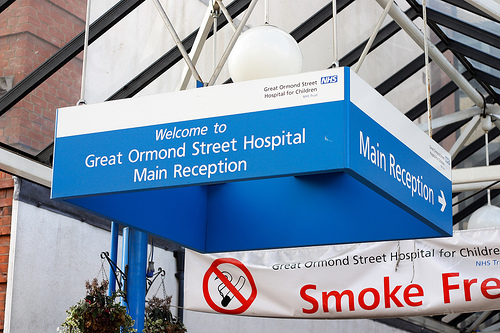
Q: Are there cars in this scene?
A: No, there are no cars.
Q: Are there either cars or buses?
A: No, there are no cars or buses.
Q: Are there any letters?
A: Yes, there are letters.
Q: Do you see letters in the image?
A: Yes, there are letters.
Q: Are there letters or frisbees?
A: Yes, there are letters.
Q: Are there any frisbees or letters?
A: Yes, there are letters.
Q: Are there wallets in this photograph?
A: No, there are no wallets.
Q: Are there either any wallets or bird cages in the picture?
A: No, there are no wallets or bird cages.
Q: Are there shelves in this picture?
A: No, there are no shelves.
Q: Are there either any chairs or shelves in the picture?
A: No, there are no shelves or chairs.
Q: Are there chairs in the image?
A: No, there are no chairs.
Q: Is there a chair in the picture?
A: No, there are no chairs.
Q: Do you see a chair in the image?
A: No, there are no chairs.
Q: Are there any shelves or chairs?
A: No, there are no chairs or shelves.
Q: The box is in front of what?
A: The box is in front of the wall.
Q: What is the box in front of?
A: The box is in front of the wall.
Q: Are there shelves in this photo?
A: No, there are no shelves.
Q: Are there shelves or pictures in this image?
A: No, there are no shelves or pictures.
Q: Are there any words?
A: Yes, there are words.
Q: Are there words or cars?
A: Yes, there are words.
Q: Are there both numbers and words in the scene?
A: No, there are words but no numbers.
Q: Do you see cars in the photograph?
A: No, there are no cars.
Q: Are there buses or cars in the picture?
A: No, there are no cars or buses.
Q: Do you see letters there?
A: Yes, there are letters.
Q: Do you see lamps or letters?
A: Yes, there are letters.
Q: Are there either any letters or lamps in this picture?
A: Yes, there are letters.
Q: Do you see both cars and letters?
A: No, there are letters but no cars.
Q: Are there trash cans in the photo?
A: No, there are no trash cans.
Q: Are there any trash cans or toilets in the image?
A: No, there are no trash cans or toilets.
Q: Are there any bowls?
A: No, there are no bowls.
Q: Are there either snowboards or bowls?
A: No, there are no bowls or snowboards.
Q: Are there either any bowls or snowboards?
A: No, there are no bowls or snowboards.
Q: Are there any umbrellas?
A: No, there are no umbrellas.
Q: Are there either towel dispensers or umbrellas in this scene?
A: No, there are no umbrellas or towel dispensers.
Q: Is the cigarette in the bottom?
A: Yes, the cigarette is in the bottom of the image.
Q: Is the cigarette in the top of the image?
A: No, the cigarette is in the bottom of the image.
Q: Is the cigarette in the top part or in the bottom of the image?
A: The cigarette is in the bottom of the image.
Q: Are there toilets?
A: No, there are no toilets.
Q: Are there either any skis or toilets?
A: No, there are no toilets or skis.